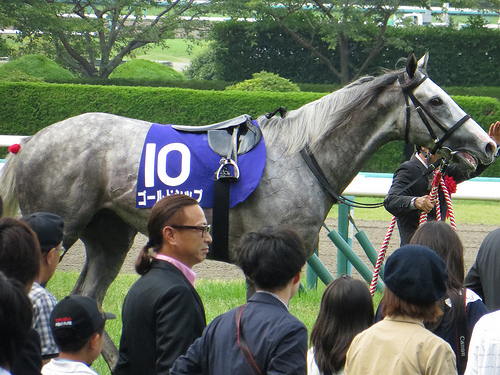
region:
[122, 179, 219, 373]
person wearing a suit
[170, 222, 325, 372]
person wearing a suit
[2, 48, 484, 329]
a gray big horse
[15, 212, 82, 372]
person is wearing a hat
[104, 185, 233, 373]
person wearing an eyeglass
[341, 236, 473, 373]
person wearing a hat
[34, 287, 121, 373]
kid wearing a hat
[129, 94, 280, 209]
a saddle on the horse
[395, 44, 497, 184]
head of a horse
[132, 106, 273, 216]
a piece of blanket beneath the saddle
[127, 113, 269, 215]
blue and white saddle blanket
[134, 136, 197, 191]
white numbers on saddle blanket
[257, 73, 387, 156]
silvery white horse mane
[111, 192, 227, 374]
man with ponytail in hair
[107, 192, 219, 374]
man with brown hair and glasses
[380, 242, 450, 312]
blue beret on woman's head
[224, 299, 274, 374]
leather strap across man's shoulder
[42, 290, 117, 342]
baseball cap on boy's head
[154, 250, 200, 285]
pink shirt collar on man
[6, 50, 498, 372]
large gray and white horse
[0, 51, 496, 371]
A silver and black race horse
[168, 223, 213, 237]
a pair of eye glasses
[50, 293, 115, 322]
a black baseball cap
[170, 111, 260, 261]
a black saddle and strap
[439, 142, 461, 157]
a bit in a horse's mouth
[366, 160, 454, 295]
a red and white lead rope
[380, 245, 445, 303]
a black beret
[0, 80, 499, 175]
a long green hedge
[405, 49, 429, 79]
the two ears of a horse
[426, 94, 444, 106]
a horse's eye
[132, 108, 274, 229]
Blue and white saddle pad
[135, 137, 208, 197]
White number 10 on saddle pad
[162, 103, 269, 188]
Black english saddle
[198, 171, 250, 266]
Black saddle strap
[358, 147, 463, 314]
Red and white lead rope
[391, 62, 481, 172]
Skinny black halter on horse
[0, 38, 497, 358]
Gray and white horse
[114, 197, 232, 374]
Japanese man with brown hair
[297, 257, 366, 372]
Short woman with dark brown hair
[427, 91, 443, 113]
Small black eye on horse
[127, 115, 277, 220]
blue cover on gray horse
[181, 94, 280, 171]
black saddle on gray horse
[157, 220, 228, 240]
eye glasses on man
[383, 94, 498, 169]
black harness on horse's face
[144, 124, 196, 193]
white 10 on blue cover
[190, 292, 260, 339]
grass growing in ground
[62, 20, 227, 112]
trees growing across street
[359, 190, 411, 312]
white and red rope